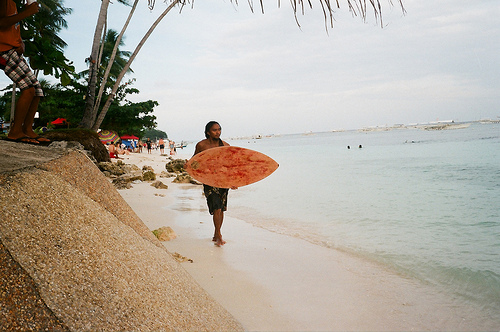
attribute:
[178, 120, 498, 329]
water — light blue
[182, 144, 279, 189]
surfboard — orange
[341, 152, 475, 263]
water — clear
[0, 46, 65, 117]
shorts — plaid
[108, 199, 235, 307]
rocks — big